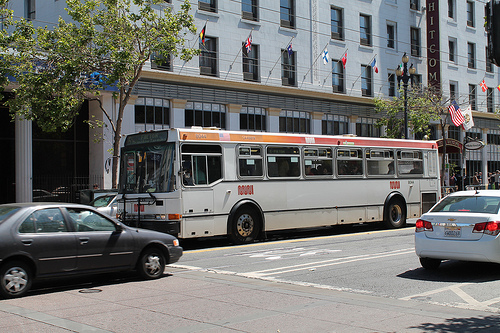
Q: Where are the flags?
A: Side of building.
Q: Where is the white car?
A: Right lane.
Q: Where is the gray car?
A: Left lane.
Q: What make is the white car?
A: Chevrolet.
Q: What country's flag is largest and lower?
A: United States.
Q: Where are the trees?
A: Sidewalk.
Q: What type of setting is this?
A: Urban.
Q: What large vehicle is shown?
A: A bus.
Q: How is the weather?
A: Sunny.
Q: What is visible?
A: Plenty of flags.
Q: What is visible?
A: Plenty of flags.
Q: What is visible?
A: Plenty of flags.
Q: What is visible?
A: Plenty of flags.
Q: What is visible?
A: Plenty of flags.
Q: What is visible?
A: Plenty of flags.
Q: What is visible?
A: Plenty of flags.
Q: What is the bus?
A: White and orange.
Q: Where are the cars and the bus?
A: Road.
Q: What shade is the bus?
A: Red and white.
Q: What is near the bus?
A: Tree.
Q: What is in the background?
A: Building.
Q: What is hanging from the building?
A: Flags.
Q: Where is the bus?
A: On the road.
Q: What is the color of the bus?
A: White.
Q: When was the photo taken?
A: Daytime.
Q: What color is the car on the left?
A: Gray.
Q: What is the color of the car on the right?
A: White.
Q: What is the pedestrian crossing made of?
A: Brick.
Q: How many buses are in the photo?
A: One.